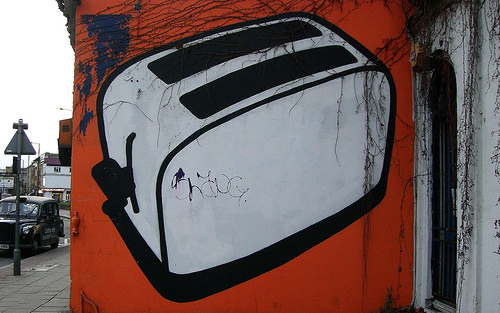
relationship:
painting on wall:
[102, 30, 360, 258] [103, 10, 482, 282]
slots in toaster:
[186, 16, 312, 109] [157, 22, 323, 199]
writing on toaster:
[172, 181, 245, 195] [157, 22, 323, 199]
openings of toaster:
[189, 19, 289, 66] [157, 22, 323, 199]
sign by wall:
[11, 119, 46, 166] [103, 10, 482, 282]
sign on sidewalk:
[11, 119, 46, 166] [23, 246, 70, 305]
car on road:
[19, 196, 46, 231] [17, 176, 86, 262]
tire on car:
[25, 238, 50, 264] [19, 196, 46, 231]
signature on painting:
[163, 169, 260, 226] [102, 30, 360, 258]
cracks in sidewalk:
[32, 262, 60, 309] [23, 246, 70, 305]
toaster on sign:
[157, 22, 323, 199] [11, 119, 46, 166]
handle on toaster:
[90, 161, 127, 193] [157, 22, 323, 199]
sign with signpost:
[11, 119, 46, 166] [10, 188, 19, 252]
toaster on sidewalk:
[157, 22, 323, 199] [23, 246, 70, 305]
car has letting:
[19, 196, 46, 231] [41, 225, 68, 249]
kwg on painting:
[171, 168, 278, 234] [102, 30, 360, 258]